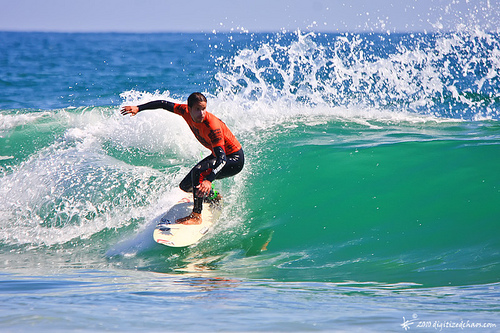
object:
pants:
[179, 147, 244, 213]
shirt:
[136, 99, 242, 181]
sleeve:
[207, 149, 227, 182]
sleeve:
[137, 100, 175, 113]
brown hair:
[188, 92, 208, 110]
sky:
[0, 0, 499, 32]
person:
[120, 92, 244, 224]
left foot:
[172, 224, 199, 225]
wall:
[234, 73, 459, 142]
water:
[0, 31, 499, 333]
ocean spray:
[199, 0, 499, 126]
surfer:
[120, 92, 245, 225]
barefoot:
[175, 213, 201, 226]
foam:
[209, 0, 500, 124]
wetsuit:
[137, 100, 245, 182]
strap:
[206, 180, 217, 200]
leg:
[179, 178, 221, 209]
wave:
[0, 87, 499, 284]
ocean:
[0, 31, 499, 127]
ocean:
[0, 105, 499, 332]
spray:
[165, 0, 500, 124]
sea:
[0, 28, 499, 333]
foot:
[207, 193, 222, 209]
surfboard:
[152, 192, 222, 247]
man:
[120, 92, 244, 225]